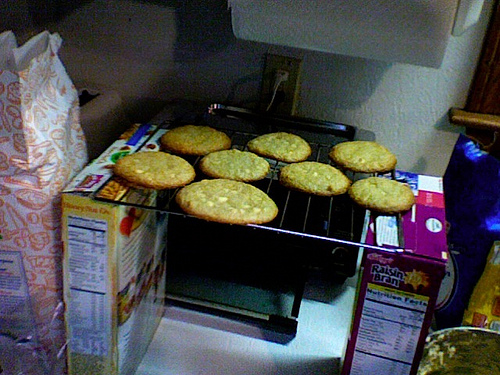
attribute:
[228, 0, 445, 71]
towels — white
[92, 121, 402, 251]
rack — wire, metal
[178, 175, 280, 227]
cookie — brown, browny, food, tasty, big, numerousy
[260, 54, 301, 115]
plug — full, occupied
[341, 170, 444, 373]
box — purple, tan, standing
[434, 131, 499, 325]
bag — blue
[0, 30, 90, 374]
bag — white, open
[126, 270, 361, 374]
counter — white